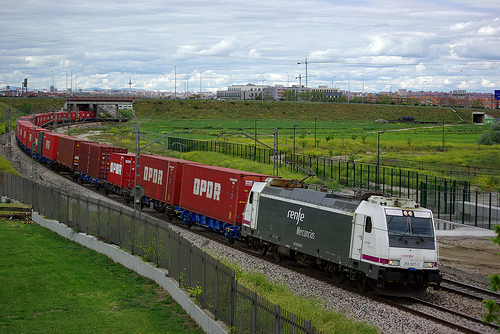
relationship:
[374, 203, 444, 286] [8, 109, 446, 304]
front of train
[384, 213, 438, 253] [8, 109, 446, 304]
windshield of train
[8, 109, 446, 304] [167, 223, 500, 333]
train on rails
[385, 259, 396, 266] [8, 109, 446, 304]
headlight in front of train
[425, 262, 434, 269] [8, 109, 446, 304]
headlight in front of train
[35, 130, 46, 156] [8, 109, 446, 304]
car of train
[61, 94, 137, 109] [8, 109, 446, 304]
bridge over train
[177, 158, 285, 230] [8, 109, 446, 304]
car of train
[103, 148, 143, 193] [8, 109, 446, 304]
car of train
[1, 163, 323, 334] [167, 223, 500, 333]
fence on side of rails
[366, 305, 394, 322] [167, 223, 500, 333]
gravel on rails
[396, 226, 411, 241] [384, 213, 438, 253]
wiper of windshield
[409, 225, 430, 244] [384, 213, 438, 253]
wiper on windshield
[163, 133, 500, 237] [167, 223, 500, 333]
fence beside rails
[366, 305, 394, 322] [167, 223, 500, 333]
gravel beside rails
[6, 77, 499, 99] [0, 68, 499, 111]
buildings in background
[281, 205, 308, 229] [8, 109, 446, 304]
lettering on train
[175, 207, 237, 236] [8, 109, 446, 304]
bottom of train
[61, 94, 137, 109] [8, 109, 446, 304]
bridge above train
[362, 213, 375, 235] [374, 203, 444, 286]
window in front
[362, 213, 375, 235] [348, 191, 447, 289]
window of cabin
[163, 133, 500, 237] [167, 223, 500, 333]
fence next to rails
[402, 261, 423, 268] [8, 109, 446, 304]
number on train